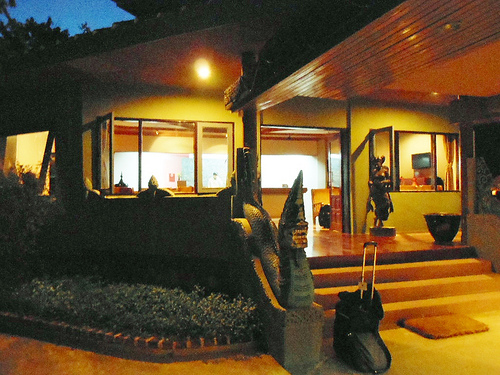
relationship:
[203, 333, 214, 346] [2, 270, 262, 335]
brick of flower bed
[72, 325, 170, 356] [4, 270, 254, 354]
brick of flower bed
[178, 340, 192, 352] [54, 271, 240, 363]
brick of flower bed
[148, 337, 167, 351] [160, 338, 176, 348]
brick of brick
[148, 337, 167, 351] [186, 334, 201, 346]
brick of brick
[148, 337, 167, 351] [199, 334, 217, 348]
brick of brick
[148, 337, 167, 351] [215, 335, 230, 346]
brick of brick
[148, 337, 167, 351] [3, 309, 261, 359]
brick of flower bed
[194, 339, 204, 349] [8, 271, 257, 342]
brick of flower bed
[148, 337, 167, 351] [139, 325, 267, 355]
brick around flower bed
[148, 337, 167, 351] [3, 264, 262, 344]
brick around flower bed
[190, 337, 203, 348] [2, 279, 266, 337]
brick around flower bed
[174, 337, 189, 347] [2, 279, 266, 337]
brick around flower bed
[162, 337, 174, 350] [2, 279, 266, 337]
brick around flower bed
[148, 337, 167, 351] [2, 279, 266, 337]
brick around flower bed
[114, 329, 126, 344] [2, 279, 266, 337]
brick around flower bed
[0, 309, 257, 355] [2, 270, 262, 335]
brick around flower bed